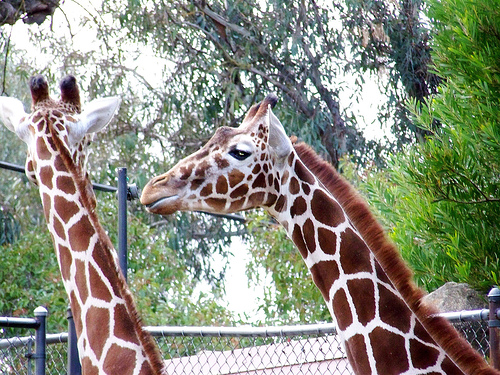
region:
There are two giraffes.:
[17, 81, 471, 373]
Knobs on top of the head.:
[21, 69, 83, 114]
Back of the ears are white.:
[0, 86, 120, 138]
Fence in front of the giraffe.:
[0, 311, 490, 373]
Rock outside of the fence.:
[412, 268, 494, 325]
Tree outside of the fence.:
[416, 15, 498, 287]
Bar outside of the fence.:
[3, 146, 283, 244]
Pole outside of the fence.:
[106, 161, 141, 295]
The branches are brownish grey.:
[176, 8, 328, 103]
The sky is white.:
[16, 8, 173, 103]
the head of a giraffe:
[95, 60, 347, 265]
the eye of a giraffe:
[221, 144, 258, 164]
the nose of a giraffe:
[130, 165, 202, 221]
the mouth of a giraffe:
[125, 163, 202, 228]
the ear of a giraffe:
[236, 70, 310, 162]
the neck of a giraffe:
[296, 105, 411, 367]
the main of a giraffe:
[241, 125, 495, 340]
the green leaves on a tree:
[388, 34, 489, 231]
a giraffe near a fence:
[216, 109, 499, 361]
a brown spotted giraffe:
[127, 49, 430, 314]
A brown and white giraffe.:
[139, 93, 494, 373]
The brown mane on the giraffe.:
[352, 200, 377, 235]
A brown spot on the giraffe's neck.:
[345, 277, 377, 324]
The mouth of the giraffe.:
[139, 173, 180, 215]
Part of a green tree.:
[459, 132, 489, 224]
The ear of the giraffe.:
[83, 95, 119, 135]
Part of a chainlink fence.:
[214, 329, 304, 374]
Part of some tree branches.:
[218, 17, 270, 80]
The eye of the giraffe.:
[227, 140, 253, 162]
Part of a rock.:
[433, 280, 482, 312]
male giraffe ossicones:
[28, 74, 80, 105]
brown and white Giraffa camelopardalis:
[139, 89, 496, 373]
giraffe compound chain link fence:
[2, 158, 497, 371]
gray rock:
[418, 280, 488, 307]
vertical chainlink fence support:
[31, 305, 46, 373]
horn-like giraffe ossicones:
[242, 93, 274, 123]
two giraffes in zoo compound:
[0, 77, 498, 372]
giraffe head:
[138, 92, 288, 222]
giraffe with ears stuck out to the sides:
[2, 75, 163, 371]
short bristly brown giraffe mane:
[287, 134, 498, 373]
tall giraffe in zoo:
[200, 96, 405, 354]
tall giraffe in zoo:
[25, 116, 152, 373]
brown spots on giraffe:
[323, 209, 373, 287]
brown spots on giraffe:
[55, 220, 103, 309]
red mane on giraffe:
[318, 149, 471, 306]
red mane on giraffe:
[93, 220, 173, 323]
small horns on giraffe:
[243, 69, 291, 116]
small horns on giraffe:
[27, 66, 87, 96]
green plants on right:
[387, 31, 492, 231]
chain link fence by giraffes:
[107, 318, 462, 373]